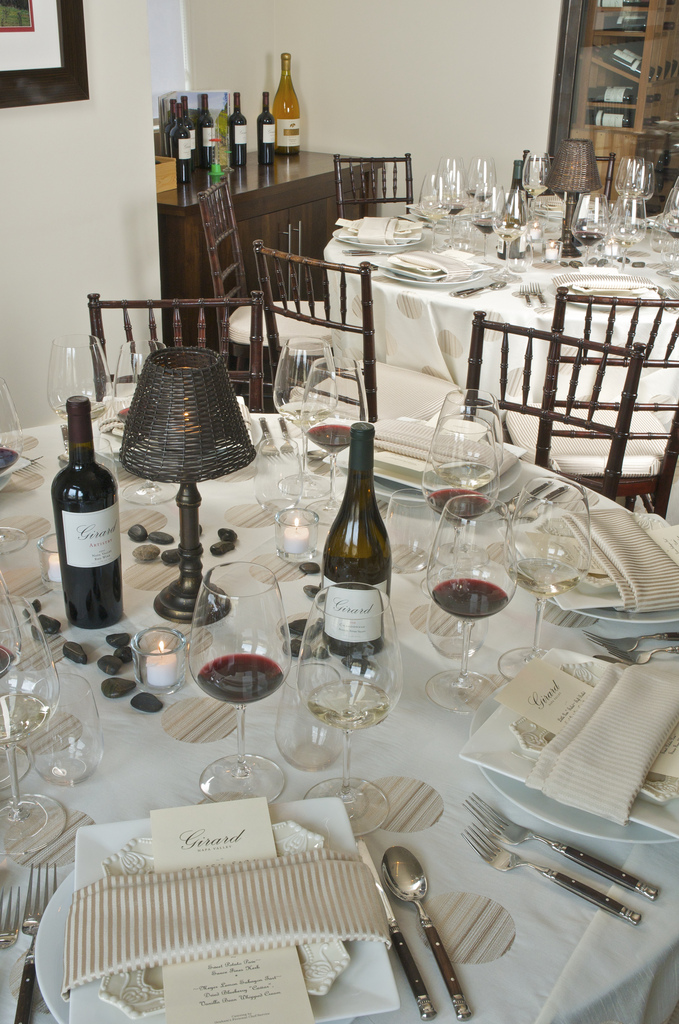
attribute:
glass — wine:
[495, 472, 591, 691]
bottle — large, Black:
[44, 390, 130, 622]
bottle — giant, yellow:
[270, 40, 308, 164]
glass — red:
[173, 553, 305, 819]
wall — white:
[0, 9, 561, 428]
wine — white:
[494, 469, 595, 686]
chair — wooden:
[249, 239, 451, 445]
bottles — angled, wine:
[601, 45, 642, 80]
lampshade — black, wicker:
[117, 340, 262, 480]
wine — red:
[196, 655, 286, 701]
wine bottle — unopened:
[50, 390, 129, 634]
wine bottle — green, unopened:
[314, 417, 394, 661]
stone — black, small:
[127, 682, 166, 716]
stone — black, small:
[103, 674, 137, 699]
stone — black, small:
[59, 638, 91, 666]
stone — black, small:
[130, 540, 163, 564]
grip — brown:
[413, 917, 472, 1020]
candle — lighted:
[131, 624, 187, 696]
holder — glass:
[131, 621, 187, 698]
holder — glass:
[273, 507, 318, 562]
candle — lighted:
[280, 514, 310, 554]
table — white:
[4, 402, 676, 1021]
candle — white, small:
[135, 624, 188, 693]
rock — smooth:
[129, 688, 167, 716]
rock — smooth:
[101, 672, 138, 700]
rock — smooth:
[60, 639, 92, 663]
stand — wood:
[155, 127, 383, 368]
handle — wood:
[412, 912, 474, 1019]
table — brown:
[154, 148, 382, 354]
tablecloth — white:
[324, 216, 677, 412]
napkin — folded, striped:
[62, 844, 395, 999]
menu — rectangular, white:
[497, 654, 678, 779]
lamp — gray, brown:
[114, 342, 257, 624]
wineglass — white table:
[435, 495, 516, 732]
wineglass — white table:
[283, 576, 418, 850]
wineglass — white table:
[181, 566, 295, 805]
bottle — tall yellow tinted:
[273, 49, 303, 165]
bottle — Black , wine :
[54, 391, 135, 632]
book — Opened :
[168, 77, 244, 116]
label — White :
[56, 498, 135, 575]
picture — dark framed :
[6, 1, 98, 114]